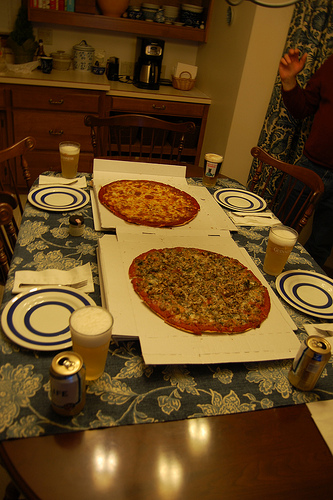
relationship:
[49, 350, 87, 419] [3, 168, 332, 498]
can on table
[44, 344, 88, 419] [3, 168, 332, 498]
can on table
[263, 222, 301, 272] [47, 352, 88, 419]
cup filled with beer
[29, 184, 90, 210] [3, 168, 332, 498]
plate on table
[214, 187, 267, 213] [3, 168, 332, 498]
plate on table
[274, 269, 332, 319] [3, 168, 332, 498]
plate on table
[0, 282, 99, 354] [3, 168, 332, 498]
plate on table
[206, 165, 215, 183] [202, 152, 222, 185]
design on glass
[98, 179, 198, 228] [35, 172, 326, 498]
pizza on table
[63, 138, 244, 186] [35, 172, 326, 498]
beer on table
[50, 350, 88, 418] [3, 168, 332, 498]
open can on table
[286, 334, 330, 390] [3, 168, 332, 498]
open can on table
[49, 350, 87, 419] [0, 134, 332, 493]
can on table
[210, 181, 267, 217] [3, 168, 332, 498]
plate on table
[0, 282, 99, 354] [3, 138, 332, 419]
plate on table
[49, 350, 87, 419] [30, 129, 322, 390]
can on table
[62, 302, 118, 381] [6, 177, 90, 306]
glass on table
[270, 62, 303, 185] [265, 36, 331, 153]
curtain hanging behind guy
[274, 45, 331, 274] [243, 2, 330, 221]
person standing in front of curtain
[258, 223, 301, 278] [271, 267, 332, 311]
beer near plate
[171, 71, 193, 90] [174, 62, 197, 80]
basket with paper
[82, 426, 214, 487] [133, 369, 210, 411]
lamps near cloth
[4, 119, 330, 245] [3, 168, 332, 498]
chairs around table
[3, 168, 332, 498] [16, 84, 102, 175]
table with closed drawers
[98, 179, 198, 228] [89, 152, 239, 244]
pizza on box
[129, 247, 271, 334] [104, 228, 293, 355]
pizza on box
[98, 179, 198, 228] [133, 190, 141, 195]
pizza has pepperoni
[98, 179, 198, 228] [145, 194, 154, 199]
pizza has pepperoni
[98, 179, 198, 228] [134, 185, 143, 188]
pizza has pepperoni